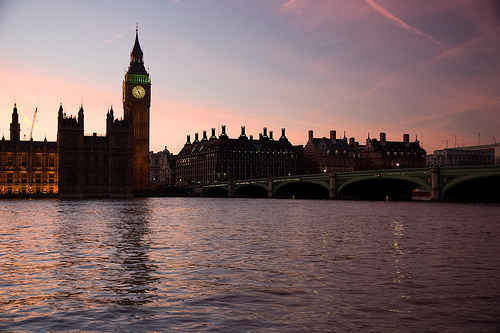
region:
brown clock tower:
[106, 32, 163, 191]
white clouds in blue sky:
[193, 33, 255, 83]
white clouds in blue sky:
[168, 56, 217, 111]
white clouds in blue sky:
[240, 26, 304, 89]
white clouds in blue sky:
[322, 37, 362, 100]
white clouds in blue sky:
[283, 55, 340, 87]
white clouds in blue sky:
[39, 10, 94, 57]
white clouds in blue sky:
[418, 26, 463, 73]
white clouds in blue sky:
[269, 41, 301, 74]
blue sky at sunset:
[5, 3, 489, 148]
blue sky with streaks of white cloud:
[4, 3, 498, 143]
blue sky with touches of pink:
[4, 0, 496, 140]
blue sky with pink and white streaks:
[4, 1, 492, 139]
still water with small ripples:
[4, 198, 498, 326]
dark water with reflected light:
[2, 190, 497, 328]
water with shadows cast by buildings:
[11, 201, 498, 331]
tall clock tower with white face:
[121, 20, 158, 191]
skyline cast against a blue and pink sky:
[14, 30, 496, 208]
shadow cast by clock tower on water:
[115, 197, 163, 317]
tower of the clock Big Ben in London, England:
[121, 21, 150, 193]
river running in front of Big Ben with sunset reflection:
[2, 194, 494, 329]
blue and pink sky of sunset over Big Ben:
[1, 3, 490, 153]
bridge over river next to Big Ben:
[200, 159, 491, 199]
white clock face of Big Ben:
[131, 83, 145, 102]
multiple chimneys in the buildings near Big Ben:
[176, 125, 417, 143]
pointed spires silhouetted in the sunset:
[55, 100, 126, 139]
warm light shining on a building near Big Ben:
[0, 137, 61, 199]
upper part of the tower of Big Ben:
[130, 24, 142, 57]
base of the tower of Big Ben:
[119, 111, 155, 196]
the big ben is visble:
[104, 19, 183, 205]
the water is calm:
[91, 149, 257, 295]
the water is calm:
[102, 209, 287, 291]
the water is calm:
[181, 245, 333, 323]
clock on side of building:
[125, 81, 147, 102]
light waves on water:
[156, 240, 253, 301]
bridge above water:
[233, 165, 420, 201]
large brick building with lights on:
[0, 135, 67, 207]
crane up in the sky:
[25, 101, 47, 139]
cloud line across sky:
[357, 3, 457, 60]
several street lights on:
[203, 167, 229, 182]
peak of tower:
[124, 20, 151, 67]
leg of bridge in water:
[425, 158, 447, 210]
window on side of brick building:
[16, 150, 35, 172]